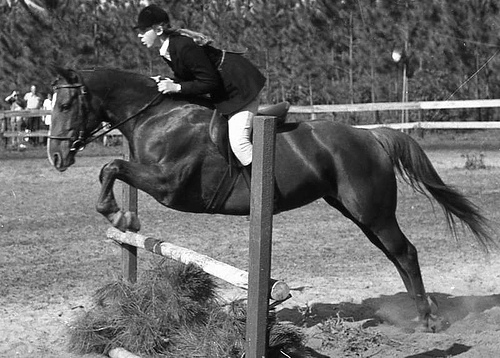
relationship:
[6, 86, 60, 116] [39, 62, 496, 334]
spectators watching horse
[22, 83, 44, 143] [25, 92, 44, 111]
man wearing shirt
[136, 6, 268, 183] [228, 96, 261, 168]
rider wearing pants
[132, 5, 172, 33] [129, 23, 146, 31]
cap has brim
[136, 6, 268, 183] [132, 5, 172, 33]
rider wears cap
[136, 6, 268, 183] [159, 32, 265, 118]
rider wears jacket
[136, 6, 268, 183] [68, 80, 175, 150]
rider holds rein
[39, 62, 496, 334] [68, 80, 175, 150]
horse wears rein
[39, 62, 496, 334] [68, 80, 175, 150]
horse wears reins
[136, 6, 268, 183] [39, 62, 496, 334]
girl rides horse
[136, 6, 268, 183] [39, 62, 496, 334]
rider jumping with horse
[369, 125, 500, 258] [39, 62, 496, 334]
tail belongs to horse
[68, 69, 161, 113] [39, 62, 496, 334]
mane belongs to horse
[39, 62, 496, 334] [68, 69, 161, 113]
horse has a mane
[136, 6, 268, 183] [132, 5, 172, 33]
rider wears helmet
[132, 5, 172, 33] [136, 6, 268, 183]
helmet belongs to rider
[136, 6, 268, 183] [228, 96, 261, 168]
rider wears pants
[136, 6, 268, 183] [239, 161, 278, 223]
rider wears boots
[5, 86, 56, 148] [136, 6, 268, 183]
people observe rider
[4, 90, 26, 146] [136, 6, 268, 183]
man takes picture of rider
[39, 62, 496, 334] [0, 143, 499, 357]
horse races in field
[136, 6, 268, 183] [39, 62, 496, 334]
rider on horse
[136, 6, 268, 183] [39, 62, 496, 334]
rider rides horse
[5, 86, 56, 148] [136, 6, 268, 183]
people watch rider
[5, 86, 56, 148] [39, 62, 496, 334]
people watch horse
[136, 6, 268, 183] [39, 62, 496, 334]
girl on horse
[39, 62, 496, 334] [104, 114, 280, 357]
horse goes over hurdle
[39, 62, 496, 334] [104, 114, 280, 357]
horse jumps over hurdle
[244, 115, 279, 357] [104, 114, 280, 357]
pole belongs to hurdle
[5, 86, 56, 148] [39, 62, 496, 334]
people observe horse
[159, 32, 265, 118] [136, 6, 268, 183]
jacket belongs to rider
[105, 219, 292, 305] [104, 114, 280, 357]
stick belongs to hurdle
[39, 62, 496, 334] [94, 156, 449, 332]
horse has legs